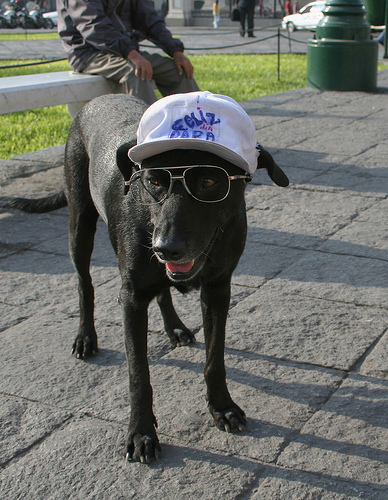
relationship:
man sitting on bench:
[52, 6, 205, 106] [4, 74, 133, 117]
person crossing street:
[228, 3, 256, 38] [6, 15, 388, 54]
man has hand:
[52, 6, 205, 106] [128, 49, 155, 80]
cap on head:
[125, 88, 261, 170] [107, 95, 296, 283]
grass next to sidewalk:
[5, 59, 387, 145] [0, 66, 387, 500]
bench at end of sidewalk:
[4, 74, 133, 117] [0, 66, 387, 500]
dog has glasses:
[64, 81, 288, 468] [125, 164, 254, 199]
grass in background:
[0, 32, 387, 158] [2, 1, 379, 141]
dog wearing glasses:
[64, 81, 288, 468] [125, 164, 254, 199]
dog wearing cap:
[64, 81, 288, 468] [125, 88, 261, 170]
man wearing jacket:
[52, 6, 205, 106] [57, 2, 185, 73]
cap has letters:
[125, 88, 261, 170] [166, 106, 219, 146]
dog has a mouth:
[64, 81, 288, 468] [159, 234, 215, 283]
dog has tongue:
[64, 81, 288, 468] [164, 258, 196, 276]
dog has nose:
[64, 81, 288, 468] [152, 233, 186, 259]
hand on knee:
[128, 49, 155, 80] [117, 53, 157, 90]